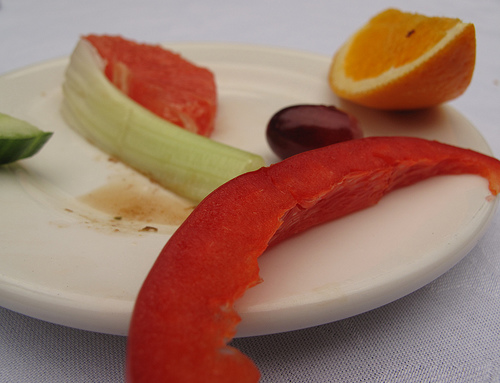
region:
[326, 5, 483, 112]
A slice of orange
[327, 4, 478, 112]
The slice is orange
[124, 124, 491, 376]
Long, red slice of food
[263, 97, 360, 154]
The grape is purple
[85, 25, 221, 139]
The fruit slice is red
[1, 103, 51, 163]
The cucumber is green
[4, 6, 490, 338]
Fruit on a plate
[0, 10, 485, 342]
The plate is round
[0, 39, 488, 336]
The plate is white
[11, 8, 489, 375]
The table cloth is white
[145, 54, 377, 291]
This is some fruits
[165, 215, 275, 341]
This is some thin watermelon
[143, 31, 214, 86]
this is a slice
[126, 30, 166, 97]
this is a slice of grapefruit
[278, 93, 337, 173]
this is a small grape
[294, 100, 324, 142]
the grape is purple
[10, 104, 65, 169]
this is a slice of a green cucoumber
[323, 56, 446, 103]
this is a rind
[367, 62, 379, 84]
this is a peel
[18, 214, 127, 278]
this is a plate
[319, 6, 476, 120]
a slice of orange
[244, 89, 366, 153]
a piece of grape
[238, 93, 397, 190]
a piece of grape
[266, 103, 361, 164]
The grape is purple.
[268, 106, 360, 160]
The grape is oval.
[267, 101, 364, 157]
The grape is on the plate.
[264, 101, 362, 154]
The grape is on the white plate.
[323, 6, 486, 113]
The fruit is orange in color.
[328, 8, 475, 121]
The orange is cut in a quarter.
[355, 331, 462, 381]
The table is gray.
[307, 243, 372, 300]
The plate is white.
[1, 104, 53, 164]
The cucumber is green.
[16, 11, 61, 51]
The wall is white.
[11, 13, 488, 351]
a plate of food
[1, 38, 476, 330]
the plate of food is white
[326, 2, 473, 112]
an orange is on the plate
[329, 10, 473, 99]
the orange is sliced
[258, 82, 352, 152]
a grape is on the plate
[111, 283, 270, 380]
this piece of food hangs off the plate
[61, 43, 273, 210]
a piece of celery is on the plate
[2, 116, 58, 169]
a piece of watermelon is on the plate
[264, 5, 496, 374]
the table cloth is white in color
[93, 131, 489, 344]
this piece of food is red in color